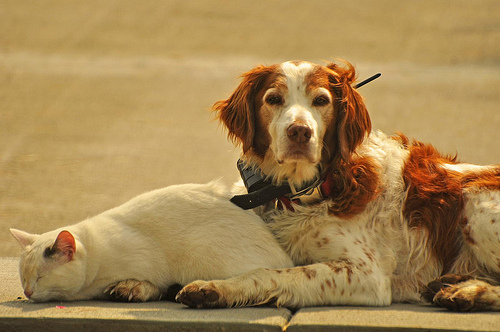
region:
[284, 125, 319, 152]
Dog has brown nose.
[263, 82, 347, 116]
Dog has brown eyes.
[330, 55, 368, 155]
Dog has brown ears.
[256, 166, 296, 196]
Dog has on black collar.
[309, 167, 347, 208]
Dog has on red collar.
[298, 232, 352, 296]
Dog has brown spots on legs.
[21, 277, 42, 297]
Cat has pink nose.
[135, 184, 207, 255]
Cat has white fur.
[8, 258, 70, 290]
Cat has eyes closed.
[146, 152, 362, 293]
Cat and dog laying on the ground.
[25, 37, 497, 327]
a dog and cat together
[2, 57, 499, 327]
a cat laying on dogs paw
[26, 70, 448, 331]
a dog laying on cat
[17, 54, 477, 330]
a cat sleeping on dogs paw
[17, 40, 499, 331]
a white cat sleeping on dogs paw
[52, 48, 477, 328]
a dog with flappy ears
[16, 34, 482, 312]
a flappy ear dog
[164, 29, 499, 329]
a white and brown dog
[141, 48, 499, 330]
dog with gps collar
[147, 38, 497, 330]
dog with red collar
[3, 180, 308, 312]
The cat is sleeping.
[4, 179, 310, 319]
The cat is white.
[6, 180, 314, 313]
The cat has short fur.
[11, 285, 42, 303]
The cat has a pink nose.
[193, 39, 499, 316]
The dog is red and white.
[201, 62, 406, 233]
The dog has a collar.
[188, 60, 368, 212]
The collar is black.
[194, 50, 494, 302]
The dog has long fur.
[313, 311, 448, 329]
The ground is brown.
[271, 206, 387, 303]
The dog has spots.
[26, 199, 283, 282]
The cat is white.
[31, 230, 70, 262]
Black on the ear.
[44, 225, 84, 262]
Inside of the ear is pink.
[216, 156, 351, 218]
The dog is wearing two collars.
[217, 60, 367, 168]
The dog has floppy ears.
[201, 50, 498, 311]
The dog is white and reddish brown.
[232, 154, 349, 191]
The collar is black.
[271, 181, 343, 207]
The collar is red.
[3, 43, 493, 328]
The animals are on a sidewalk.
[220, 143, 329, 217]
dog's bark control collar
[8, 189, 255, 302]
white cat laying down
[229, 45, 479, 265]
brown and white dog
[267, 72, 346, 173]
brown and white dog's face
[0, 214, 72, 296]
white cat's head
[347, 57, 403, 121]
antenna from dog's collar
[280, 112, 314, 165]
dog's nose and mouth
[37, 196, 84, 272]
cat's ear with black spot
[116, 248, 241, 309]
brown and white dog's front paws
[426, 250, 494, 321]
brown and white dog's back paws